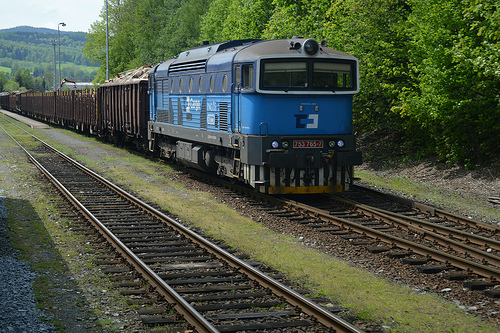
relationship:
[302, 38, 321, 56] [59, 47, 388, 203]
guide light on train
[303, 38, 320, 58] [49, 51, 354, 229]
guide light on train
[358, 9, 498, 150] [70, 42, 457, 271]
bushes on side of train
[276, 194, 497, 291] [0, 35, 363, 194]
tracks of train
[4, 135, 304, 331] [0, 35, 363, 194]
tracks of train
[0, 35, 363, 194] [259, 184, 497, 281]
train on tracks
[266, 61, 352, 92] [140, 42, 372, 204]
windshield of train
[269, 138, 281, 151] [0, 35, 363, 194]
headlight on train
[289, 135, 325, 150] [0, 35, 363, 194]
numbers of train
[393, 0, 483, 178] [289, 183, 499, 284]
tree on side of track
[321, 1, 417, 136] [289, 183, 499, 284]
tree on side of track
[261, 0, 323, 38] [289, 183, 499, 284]
tree on side of track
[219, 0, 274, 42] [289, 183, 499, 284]
tree on side of track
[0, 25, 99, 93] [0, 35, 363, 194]
mountain behind train